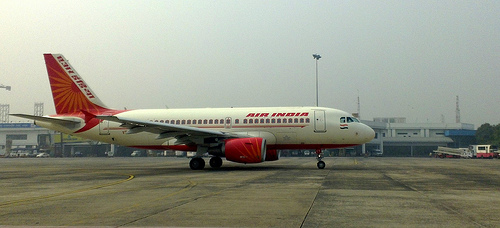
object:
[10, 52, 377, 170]
plane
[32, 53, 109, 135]
tail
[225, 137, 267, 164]
engine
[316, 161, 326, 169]
wheel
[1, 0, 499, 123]
sky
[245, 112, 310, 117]
lettering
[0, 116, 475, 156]
building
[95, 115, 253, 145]
wing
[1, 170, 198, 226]
line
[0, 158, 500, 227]
ground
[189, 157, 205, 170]
wheel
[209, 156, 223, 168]
wheel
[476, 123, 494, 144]
tree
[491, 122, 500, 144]
tree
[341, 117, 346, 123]
window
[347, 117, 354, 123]
window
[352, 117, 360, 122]
window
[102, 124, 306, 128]
line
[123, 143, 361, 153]
underside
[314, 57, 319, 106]
pole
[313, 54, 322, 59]
light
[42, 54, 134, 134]
design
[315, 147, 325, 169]
landing gear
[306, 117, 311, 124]
window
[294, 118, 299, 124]
window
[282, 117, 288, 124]
window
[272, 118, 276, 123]
window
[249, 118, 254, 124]
window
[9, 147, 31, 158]
vehicle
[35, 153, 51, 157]
vehicle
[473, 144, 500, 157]
vehicle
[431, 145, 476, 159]
vehicle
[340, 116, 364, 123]
cockpit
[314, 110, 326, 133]
door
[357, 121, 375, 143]
tip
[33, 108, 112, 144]
back